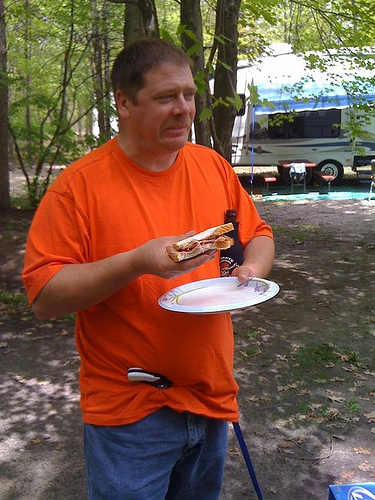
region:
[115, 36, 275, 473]
man is eating outside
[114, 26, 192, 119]
man has brown hair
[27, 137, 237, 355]
man has orange shirt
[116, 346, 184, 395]
white item around man's waist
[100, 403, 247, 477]
man wears blue jeans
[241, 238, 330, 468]
ground is brown and dead near man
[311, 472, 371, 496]
blue beer container next to man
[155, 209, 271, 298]
man is holding sandwich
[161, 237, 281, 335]
man holds white plate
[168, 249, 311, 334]
white plate is circular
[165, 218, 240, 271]
meat and white bread sandwich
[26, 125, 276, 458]
men's orange tee shirt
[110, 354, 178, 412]
pistol with white handle grip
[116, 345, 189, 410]
pistol in waistband of pants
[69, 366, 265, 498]
men's blue denim pants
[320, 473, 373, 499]
bottom left corner of a Bud Light box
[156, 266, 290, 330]
round flowered paper plate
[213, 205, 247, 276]
beer bottle in crook of arm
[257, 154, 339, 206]
red picnic table with benches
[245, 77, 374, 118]
blue roll out awning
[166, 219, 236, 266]
sandwich in man's hand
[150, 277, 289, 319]
paper plate in man's hand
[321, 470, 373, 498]
box of beer on ground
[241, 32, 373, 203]
camper in the woods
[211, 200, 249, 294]
bottle of beer in man's arm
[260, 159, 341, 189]
picnic table and benches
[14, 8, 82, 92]
green leaves on a tree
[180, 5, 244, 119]
trunks of a tree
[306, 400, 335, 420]
brown leaves on the ground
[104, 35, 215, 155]
face of a man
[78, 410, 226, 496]
a man's blue jean pants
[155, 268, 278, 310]
a white paper plate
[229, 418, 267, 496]
part of a blue stick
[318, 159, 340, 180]
the tire of a motor home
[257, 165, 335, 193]
a red picnic table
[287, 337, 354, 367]
a small patch of grass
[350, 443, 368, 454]
a brown leaf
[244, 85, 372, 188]
a blue canopy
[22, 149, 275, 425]
a man's orange t-shirt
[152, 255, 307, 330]
A white plate.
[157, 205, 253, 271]
A sandwich half eaten.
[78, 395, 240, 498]
a pair of blue jeans.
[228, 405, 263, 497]
a pole in the ground.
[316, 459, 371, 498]
a case of beer.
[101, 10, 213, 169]
a man with dark hair.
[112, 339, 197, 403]
a gun in a man's pants.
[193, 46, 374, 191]
a trailer in a field.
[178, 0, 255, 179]
a tree in a field.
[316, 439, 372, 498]
an object on the ground.